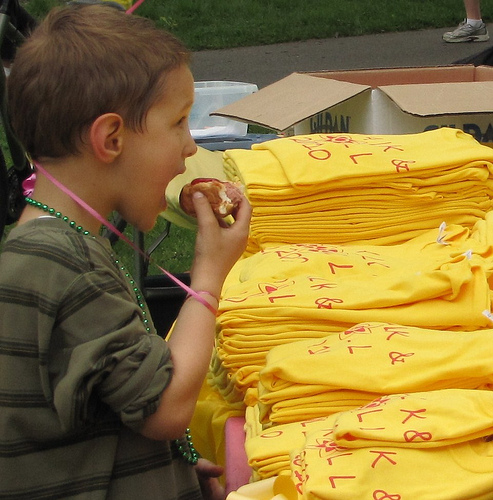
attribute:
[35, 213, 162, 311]
beads — shiny, green, plastic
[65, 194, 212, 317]
ribbon — pink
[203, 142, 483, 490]
shirts — yellow, red, yelow, stacked, folded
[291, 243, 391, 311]
writing — red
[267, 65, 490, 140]
box — open, cardboard, white, empty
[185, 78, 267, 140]
tub — transluscent, plastic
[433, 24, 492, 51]
sneakers — gray, white, grey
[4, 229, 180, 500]
shirt — black, green, long sleeve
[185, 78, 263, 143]
container — plastic, clear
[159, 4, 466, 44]
grass — green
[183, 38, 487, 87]
sidewalk — grey, cemet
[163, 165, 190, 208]
mouth — open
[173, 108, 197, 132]
eyes — open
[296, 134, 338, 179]
letters — red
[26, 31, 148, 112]
hair — brown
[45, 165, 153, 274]
string — pink